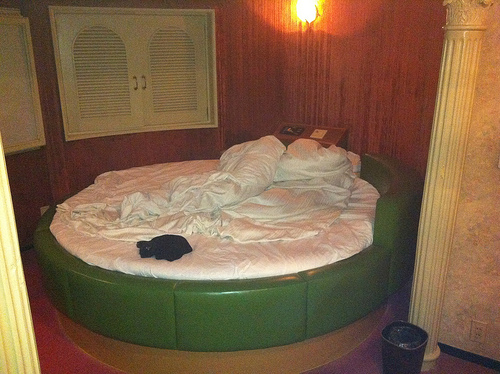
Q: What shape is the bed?
A: Circle.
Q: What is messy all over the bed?
A: Blankets.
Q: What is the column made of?
A: Wood.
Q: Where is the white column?
A: Against the wall.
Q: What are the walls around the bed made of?
A: Wood.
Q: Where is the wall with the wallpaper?
A: By the column.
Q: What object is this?
A: Bed.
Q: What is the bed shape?
A: Round.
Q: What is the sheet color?
A: White.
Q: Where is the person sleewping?
A: Bed.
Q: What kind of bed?
A: Leather.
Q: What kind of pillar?
A: Roman design.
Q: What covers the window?
A: Shutter.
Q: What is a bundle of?
A: Sheets.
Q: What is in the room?
A: A bed.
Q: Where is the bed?
A: In a room.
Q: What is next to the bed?
A: Wall.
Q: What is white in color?
A: Shades next to bed.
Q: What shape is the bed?
A: Round.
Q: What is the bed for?
A: Laying.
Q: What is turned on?
A: The light.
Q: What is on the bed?
A: Sheets.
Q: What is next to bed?
A: Pole.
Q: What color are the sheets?
A: White.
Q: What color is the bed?
A: Green.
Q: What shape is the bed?
A: Round.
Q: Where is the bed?
A: In the corner.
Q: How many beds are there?
A: One.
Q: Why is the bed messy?
A: It has not been made.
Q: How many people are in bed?
A: One.